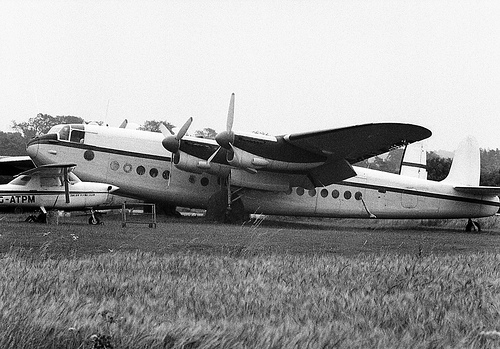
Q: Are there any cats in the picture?
A: No, there are no cats.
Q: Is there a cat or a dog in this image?
A: No, there are no cats or dogs.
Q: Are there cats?
A: No, there are no cats.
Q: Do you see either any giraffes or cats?
A: No, there are no cats or giraffes.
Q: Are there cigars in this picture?
A: No, there are no cigars.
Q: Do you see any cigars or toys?
A: No, there are no cigars or toys.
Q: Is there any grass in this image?
A: Yes, there is grass.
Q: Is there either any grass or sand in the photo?
A: Yes, there is grass.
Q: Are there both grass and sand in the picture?
A: No, there is grass but no sand.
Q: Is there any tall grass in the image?
A: Yes, there is tall grass.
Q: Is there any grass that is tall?
A: Yes, there is grass that is tall.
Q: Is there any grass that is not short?
A: Yes, there is tall grass.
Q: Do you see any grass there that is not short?
A: Yes, there is tall grass.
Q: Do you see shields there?
A: No, there are no shields.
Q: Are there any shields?
A: No, there are no shields.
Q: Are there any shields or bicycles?
A: No, there are no shields or bicycles.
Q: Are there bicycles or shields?
A: No, there are no shields or bicycles.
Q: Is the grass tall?
A: Yes, the grass is tall.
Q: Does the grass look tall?
A: Yes, the grass is tall.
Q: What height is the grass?
A: The grass is tall.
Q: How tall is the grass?
A: The grass is tall.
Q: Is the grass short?
A: No, the grass is tall.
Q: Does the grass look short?
A: No, the grass is tall.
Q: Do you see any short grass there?
A: No, there is grass but it is tall.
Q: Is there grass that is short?
A: No, there is grass but it is tall.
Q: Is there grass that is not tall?
A: No, there is grass but it is tall.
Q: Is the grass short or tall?
A: The grass is tall.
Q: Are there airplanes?
A: Yes, there is an airplane.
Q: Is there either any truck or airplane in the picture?
A: Yes, there is an airplane.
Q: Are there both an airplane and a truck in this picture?
A: No, there is an airplane but no trucks.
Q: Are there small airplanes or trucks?
A: Yes, there is a small airplane.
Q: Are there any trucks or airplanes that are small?
A: Yes, the airplane is small.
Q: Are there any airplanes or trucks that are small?
A: Yes, the airplane is small.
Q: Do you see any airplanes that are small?
A: Yes, there is a small airplane.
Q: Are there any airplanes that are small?
A: Yes, there is a small airplane.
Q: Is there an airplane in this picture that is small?
A: Yes, there is an airplane that is small.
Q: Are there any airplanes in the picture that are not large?
A: Yes, there is a small airplane.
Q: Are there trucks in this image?
A: No, there are no trucks.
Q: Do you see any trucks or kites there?
A: No, there are no trucks or kites.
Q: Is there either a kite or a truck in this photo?
A: No, there are no trucks or kites.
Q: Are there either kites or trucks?
A: No, there are no trucks or kites.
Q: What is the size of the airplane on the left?
A: The airplane is small.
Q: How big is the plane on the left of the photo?
A: The airplane is small.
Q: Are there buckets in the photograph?
A: No, there are no buckets.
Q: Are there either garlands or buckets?
A: No, there are no buckets or garlands.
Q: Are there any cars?
A: No, there are no cars.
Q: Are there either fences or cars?
A: No, there are no cars or fences.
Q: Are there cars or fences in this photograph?
A: No, there are no cars or fences.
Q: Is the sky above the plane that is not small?
A: Yes, the sky is above the airplane.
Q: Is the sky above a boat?
A: No, the sky is above the airplane.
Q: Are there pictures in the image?
A: No, there are no pictures.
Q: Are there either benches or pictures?
A: No, there are no pictures or benches.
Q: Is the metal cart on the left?
A: Yes, the cart is on the left of the image.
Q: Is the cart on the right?
A: No, the cart is on the left of the image.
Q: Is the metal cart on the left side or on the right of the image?
A: The cart is on the left of the image.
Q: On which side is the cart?
A: The cart is on the left of the image.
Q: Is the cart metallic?
A: Yes, the cart is metallic.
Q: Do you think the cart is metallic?
A: Yes, the cart is metallic.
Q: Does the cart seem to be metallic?
A: Yes, the cart is metallic.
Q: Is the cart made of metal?
A: Yes, the cart is made of metal.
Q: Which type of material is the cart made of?
A: The cart is made of metal.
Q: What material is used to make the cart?
A: The cart is made of metal.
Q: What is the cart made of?
A: The cart is made of metal.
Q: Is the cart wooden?
A: No, the cart is metallic.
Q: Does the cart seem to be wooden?
A: No, the cart is metallic.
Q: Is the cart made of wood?
A: No, the cart is made of metal.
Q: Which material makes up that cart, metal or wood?
A: The cart is made of metal.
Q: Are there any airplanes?
A: Yes, there is an airplane.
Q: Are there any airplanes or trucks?
A: Yes, there is an airplane.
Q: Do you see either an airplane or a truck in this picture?
A: Yes, there is an airplane.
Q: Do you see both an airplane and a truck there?
A: No, there is an airplane but no trucks.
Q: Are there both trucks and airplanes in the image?
A: No, there is an airplane but no trucks.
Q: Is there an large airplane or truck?
A: Yes, there is a large airplane.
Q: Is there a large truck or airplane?
A: Yes, there is a large airplane.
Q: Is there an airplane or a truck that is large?
A: Yes, the airplane is large.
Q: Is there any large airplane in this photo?
A: Yes, there is a large airplane.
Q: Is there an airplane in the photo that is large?
A: Yes, there is an airplane that is large.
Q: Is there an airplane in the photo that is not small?
A: Yes, there is a large airplane.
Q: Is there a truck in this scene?
A: No, there are no trucks.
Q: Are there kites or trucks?
A: No, there are no trucks or kites.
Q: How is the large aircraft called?
A: The aircraft is an airplane.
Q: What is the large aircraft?
A: The aircraft is an airplane.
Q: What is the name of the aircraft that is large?
A: The aircraft is an airplane.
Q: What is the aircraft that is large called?
A: The aircraft is an airplane.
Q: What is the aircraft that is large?
A: The aircraft is an airplane.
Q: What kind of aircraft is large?
A: The aircraft is an airplane.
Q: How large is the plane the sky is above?
A: The plane is large.